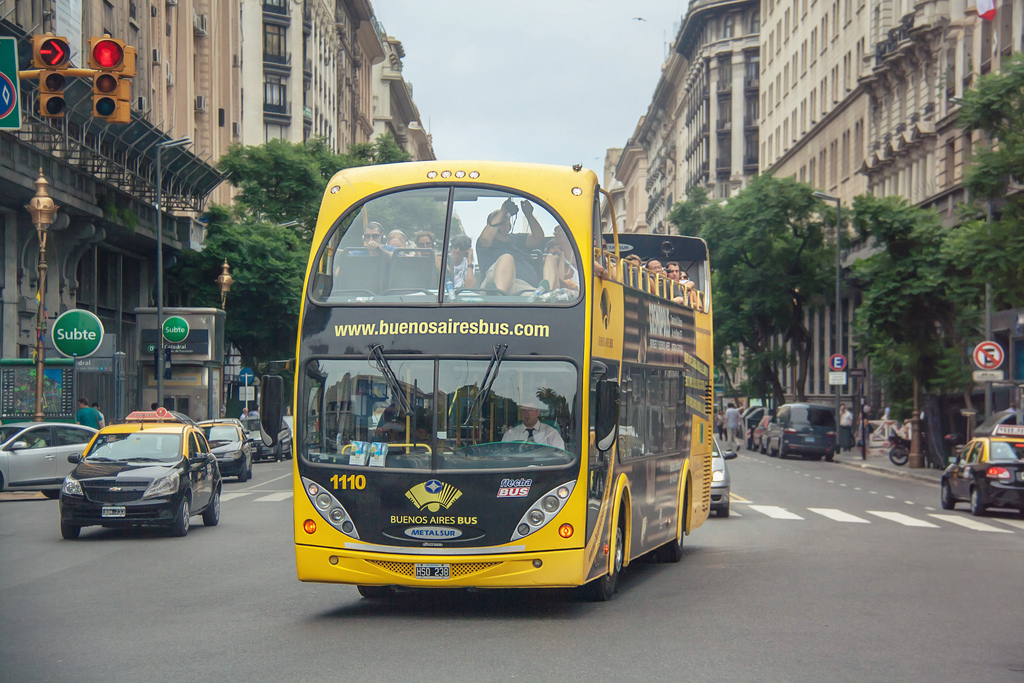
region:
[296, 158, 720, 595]
yellow double Decker tour bus in the city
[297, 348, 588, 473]
drivers front windshield on the tour bus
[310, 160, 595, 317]
upper deck windshield of the tour bus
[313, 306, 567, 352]
business brand name displayed on the bus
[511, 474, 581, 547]
front headlight of the tour bus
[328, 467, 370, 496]
identification number of the tour bus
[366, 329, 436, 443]
windshield wiper on the front windshield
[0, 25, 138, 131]
traffic lights mounted over the city street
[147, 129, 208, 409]
street lights on the side of the road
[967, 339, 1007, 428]
traffic signs on the street curb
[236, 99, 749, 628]
shiny yellow double deck bus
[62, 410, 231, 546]
black and yellow car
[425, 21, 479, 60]
white clouds in blue sky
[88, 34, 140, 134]
red signal light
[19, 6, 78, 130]
red light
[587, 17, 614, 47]
white clouds in blue sky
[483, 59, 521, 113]
white clouds in blue sky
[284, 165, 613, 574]
a bus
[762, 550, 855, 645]
the street is grey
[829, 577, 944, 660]
the street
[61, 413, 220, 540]
a car in the street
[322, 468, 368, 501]
number on the bus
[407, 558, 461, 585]
a license plate on the bus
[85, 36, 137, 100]
a traffic signal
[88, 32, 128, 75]
a red light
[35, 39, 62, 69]
a red arrow